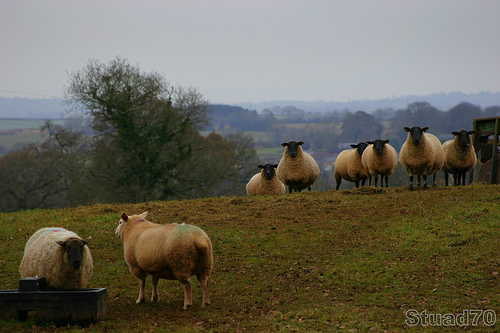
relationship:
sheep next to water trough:
[19, 226, 94, 289] [1, 274, 108, 322]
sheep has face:
[19, 226, 94, 289] [56, 234, 94, 270]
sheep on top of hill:
[398, 124, 446, 188] [0, 184, 500, 331]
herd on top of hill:
[246, 125, 479, 194] [0, 184, 500, 331]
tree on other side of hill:
[66, 57, 210, 202] [0, 184, 500, 331]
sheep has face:
[113, 208, 216, 309] [115, 214, 126, 237]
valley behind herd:
[0, 119, 499, 210] [246, 125, 479, 194]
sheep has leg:
[439, 130, 477, 187] [444, 171, 449, 187]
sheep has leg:
[439, 130, 477, 187] [452, 171, 460, 185]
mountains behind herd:
[237, 91, 499, 119] [246, 125, 479, 194]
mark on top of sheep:
[176, 223, 195, 235] [113, 208, 216, 309]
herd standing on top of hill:
[246, 125, 479, 194] [0, 184, 500, 331]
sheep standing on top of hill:
[332, 141, 367, 189] [0, 184, 500, 331]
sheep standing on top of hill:
[274, 140, 322, 193] [0, 184, 500, 331]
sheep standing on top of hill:
[439, 130, 477, 187] [0, 184, 500, 331]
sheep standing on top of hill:
[359, 139, 398, 188] [0, 184, 500, 331]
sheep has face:
[274, 140, 322, 193] [282, 140, 305, 158]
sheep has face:
[439, 130, 477, 187] [451, 129, 478, 149]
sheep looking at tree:
[113, 208, 216, 309] [66, 57, 210, 202]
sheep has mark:
[113, 208, 216, 309] [176, 223, 195, 235]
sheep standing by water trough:
[113, 208, 216, 309] [1, 274, 108, 322]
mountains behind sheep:
[237, 91, 499, 119] [398, 124, 446, 188]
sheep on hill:
[113, 208, 216, 309] [0, 184, 500, 331]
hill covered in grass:
[0, 184, 500, 331] [1, 182, 499, 332]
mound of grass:
[342, 186, 386, 196] [1, 182, 499, 332]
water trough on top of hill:
[1, 274, 108, 322] [0, 184, 500, 331]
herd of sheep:
[246, 125, 479, 194] [274, 140, 322, 193]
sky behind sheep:
[0, 1, 500, 104] [398, 124, 446, 188]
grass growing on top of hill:
[1, 182, 499, 332] [0, 184, 500, 331]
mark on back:
[176, 223, 195, 235] [143, 223, 203, 241]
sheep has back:
[113, 208, 216, 309] [143, 223, 203, 241]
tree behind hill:
[66, 57, 210, 202] [0, 184, 500, 331]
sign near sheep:
[466, 116, 499, 182] [439, 130, 477, 187]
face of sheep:
[282, 140, 305, 158] [274, 140, 322, 193]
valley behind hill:
[0, 119, 499, 210] [0, 184, 500, 331]